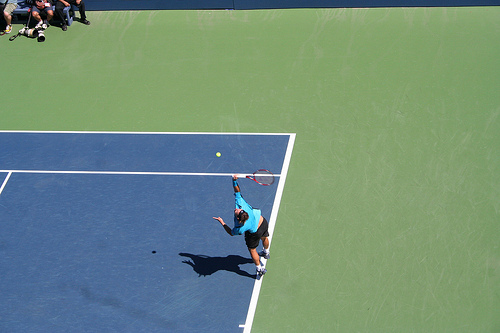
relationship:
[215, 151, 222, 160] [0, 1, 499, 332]
ball in air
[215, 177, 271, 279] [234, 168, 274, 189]
man has a racket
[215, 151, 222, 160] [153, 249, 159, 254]
ball has a shadow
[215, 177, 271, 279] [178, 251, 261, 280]
man has a shadow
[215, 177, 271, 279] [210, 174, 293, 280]
man in motion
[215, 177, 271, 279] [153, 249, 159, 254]
man has a shadow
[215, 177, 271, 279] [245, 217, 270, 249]
man has on shorts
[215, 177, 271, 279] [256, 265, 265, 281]
man has a shoe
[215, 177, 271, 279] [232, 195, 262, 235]
man has a shirt